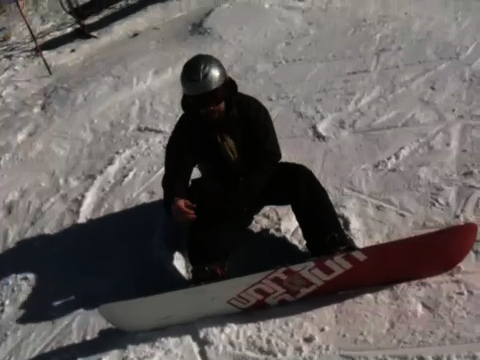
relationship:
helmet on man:
[161, 56, 248, 106] [142, 32, 324, 279]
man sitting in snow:
[162, 54, 359, 287] [271, 17, 478, 193]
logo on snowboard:
[227, 251, 367, 311] [96, 220, 477, 335]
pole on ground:
[13, 0, 52, 77] [1, 1, 479, 358]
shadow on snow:
[0, 198, 193, 360] [262, 32, 462, 292]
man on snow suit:
[162, 54, 359, 287] [164, 111, 369, 261]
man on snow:
[162, 54, 359, 287] [2, 4, 479, 359]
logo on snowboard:
[227, 251, 367, 311] [76, 214, 477, 330]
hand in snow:
[170, 197, 198, 224] [2, 4, 479, 359]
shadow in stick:
[94, 11, 127, 31] [58, 1, 88, 25]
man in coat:
[154, 54, 370, 269] [154, 107, 272, 209]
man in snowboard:
[154, 54, 370, 269] [97, 222, 477, 334]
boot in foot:
[300, 229, 360, 253] [189, 262, 230, 281]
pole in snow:
[11, 0, 72, 91] [13, 57, 158, 164]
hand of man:
[173, 198, 197, 219] [162, 54, 359, 287]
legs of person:
[193, 163, 357, 251] [162, 52, 362, 250]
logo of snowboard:
[220, 249, 369, 314] [96, 220, 477, 335]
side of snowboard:
[97, 221, 477, 309] [96, 220, 477, 335]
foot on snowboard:
[310, 236, 362, 256] [76, 214, 477, 330]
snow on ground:
[312, 20, 435, 164] [462, 140, 476, 169]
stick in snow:
[14, 26, 123, 93] [20, 56, 106, 142]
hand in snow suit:
[171, 199, 196, 225] [96, 54, 477, 332]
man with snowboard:
[162, 54, 359, 287] [96, 220, 477, 335]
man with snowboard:
[162, 54, 359, 287] [76, 214, 477, 330]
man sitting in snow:
[162, 54, 359, 287] [378, 63, 478, 198]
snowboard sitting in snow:
[76, 214, 477, 330] [378, 63, 478, 198]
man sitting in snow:
[162, 54, 359, 287] [321, 62, 408, 202]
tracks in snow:
[3, 5, 472, 358] [2, 4, 479, 359]